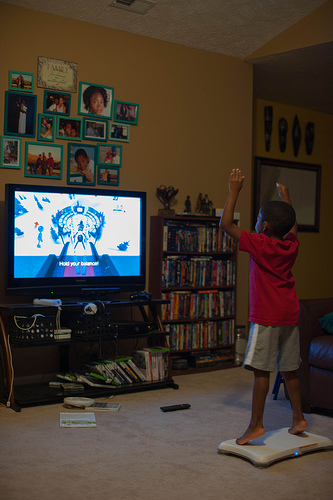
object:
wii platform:
[213, 424, 325, 460]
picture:
[80, 84, 112, 116]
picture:
[114, 103, 135, 122]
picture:
[10, 74, 32, 90]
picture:
[69, 144, 95, 183]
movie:
[195, 258, 202, 287]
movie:
[179, 290, 184, 321]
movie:
[207, 323, 212, 351]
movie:
[205, 225, 210, 253]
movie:
[206, 256, 213, 289]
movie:
[168, 291, 173, 323]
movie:
[190, 322, 196, 350]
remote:
[158, 401, 192, 411]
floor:
[0, 364, 332, 499]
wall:
[0, 0, 253, 388]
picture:
[46, 92, 70, 114]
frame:
[41, 88, 70, 118]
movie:
[169, 291, 174, 323]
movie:
[190, 293, 195, 318]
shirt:
[236, 231, 300, 330]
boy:
[218, 168, 309, 446]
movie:
[211, 258, 216, 290]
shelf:
[162, 250, 237, 259]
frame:
[112, 96, 141, 129]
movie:
[226, 291, 230, 316]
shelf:
[158, 314, 238, 326]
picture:
[6, 94, 33, 134]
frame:
[0, 89, 38, 140]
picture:
[58, 118, 80, 140]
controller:
[129, 290, 150, 303]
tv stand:
[0, 297, 180, 414]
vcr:
[211, 227, 219, 252]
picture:
[39, 118, 55, 140]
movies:
[161, 261, 166, 290]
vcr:
[110, 319, 152, 337]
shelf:
[0, 296, 171, 317]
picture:
[84, 119, 104, 138]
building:
[0, 0, 332, 499]